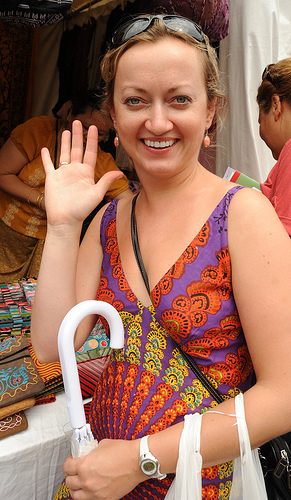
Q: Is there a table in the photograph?
A: Yes, there is a table.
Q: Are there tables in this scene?
A: Yes, there is a table.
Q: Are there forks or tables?
A: Yes, there is a table.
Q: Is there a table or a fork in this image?
A: Yes, there is a table.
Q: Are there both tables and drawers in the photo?
A: No, there is a table but no drawers.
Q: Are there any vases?
A: No, there are no vases.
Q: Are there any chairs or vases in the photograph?
A: No, there are no vases or chairs.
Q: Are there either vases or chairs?
A: No, there are no vases or chairs.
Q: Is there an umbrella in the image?
A: Yes, there is an umbrella.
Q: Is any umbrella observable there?
A: Yes, there is an umbrella.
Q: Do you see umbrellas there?
A: Yes, there is an umbrella.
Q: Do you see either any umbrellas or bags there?
A: Yes, there is an umbrella.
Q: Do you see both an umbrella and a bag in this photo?
A: Yes, there are both an umbrella and a bag.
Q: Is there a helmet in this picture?
A: No, there are no helmets.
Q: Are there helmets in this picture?
A: No, there are no helmets.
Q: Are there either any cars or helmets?
A: No, there are no helmets or cars.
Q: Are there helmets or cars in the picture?
A: No, there are no helmets or cars.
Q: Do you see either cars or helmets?
A: No, there are no helmets or cars.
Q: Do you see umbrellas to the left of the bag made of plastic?
A: Yes, there is an umbrella to the left of the bag.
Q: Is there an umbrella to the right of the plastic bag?
A: No, the umbrella is to the left of the bag.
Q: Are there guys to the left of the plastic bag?
A: No, there is an umbrella to the left of the bag.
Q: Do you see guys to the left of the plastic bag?
A: No, there is an umbrella to the left of the bag.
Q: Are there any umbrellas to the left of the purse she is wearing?
A: Yes, there is an umbrella to the left of the purse.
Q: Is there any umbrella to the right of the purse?
A: No, the umbrella is to the left of the purse.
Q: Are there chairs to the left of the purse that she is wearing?
A: No, there is an umbrella to the left of the purse.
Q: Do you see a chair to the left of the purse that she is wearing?
A: No, there is an umbrella to the left of the purse.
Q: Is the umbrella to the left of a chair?
A: No, the umbrella is to the left of a purse.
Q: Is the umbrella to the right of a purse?
A: No, the umbrella is to the left of a purse.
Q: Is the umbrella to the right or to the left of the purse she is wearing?
A: The umbrella is to the left of the purse.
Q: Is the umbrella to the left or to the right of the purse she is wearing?
A: The umbrella is to the left of the purse.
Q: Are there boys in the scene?
A: No, there are no boys.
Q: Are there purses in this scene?
A: Yes, there is a purse.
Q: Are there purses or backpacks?
A: Yes, there is a purse.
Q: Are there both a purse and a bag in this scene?
A: Yes, there are both a purse and a bag.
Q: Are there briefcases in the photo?
A: No, there are no briefcases.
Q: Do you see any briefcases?
A: No, there are no briefcases.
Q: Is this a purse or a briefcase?
A: This is a purse.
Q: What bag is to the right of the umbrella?
A: The bag is a purse.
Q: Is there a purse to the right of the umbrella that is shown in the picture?
A: Yes, there is a purse to the right of the umbrella.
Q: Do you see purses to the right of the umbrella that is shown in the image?
A: Yes, there is a purse to the right of the umbrella.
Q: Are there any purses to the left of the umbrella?
A: No, the purse is to the right of the umbrella.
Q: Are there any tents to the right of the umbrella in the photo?
A: No, there is a purse to the right of the umbrella.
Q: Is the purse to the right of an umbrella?
A: Yes, the purse is to the right of an umbrella.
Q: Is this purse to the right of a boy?
A: No, the purse is to the right of an umbrella.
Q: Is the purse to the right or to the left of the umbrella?
A: The purse is to the right of the umbrella.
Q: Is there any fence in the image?
A: No, there are no fences.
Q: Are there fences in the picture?
A: No, there are no fences.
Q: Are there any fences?
A: No, there are no fences.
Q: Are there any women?
A: Yes, there is a woman.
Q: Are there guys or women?
A: Yes, there is a woman.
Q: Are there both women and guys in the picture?
A: No, there is a woman but no guys.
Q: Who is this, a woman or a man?
A: This is a woman.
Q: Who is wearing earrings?
A: The woman is wearing earrings.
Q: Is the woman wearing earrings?
A: Yes, the woman is wearing earrings.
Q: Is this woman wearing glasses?
A: No, the woman is wearing earrings.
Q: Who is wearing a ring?
A: The woman is wearing a ring.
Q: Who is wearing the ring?
A: The woman is wearing a ring.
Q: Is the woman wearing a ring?
A: Yes, the woman is wearing a ring.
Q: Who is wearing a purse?
A: The woman is wearing a purse.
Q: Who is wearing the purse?
A: The woman is wearing a purse.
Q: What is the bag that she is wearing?
A: The bag is a purse.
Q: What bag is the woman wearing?
A: The woman is wearing a purse.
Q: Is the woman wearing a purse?
A: Yes, the woman is wearing a purse.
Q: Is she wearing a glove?
A: No, the woman is wearing a purse.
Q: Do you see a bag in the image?
A: Yes, there is a bag.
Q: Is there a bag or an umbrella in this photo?
A: Yes, there is a bag.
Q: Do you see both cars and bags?
A: No, there is a bag but no cars.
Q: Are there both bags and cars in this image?
A: No, there is a bag but no cars.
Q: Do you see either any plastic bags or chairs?
A: Yes, there is a plastic bag.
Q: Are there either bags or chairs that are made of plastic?
A: Yes, the bag is made of plastic.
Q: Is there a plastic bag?
A: Yes, there is a bag that is made of plastic.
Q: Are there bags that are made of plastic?
A: Yes, there is a bag that is made of plastic.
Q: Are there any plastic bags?
A: Yes, there is a bag that is made of plastic.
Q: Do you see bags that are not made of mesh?
A: Yes, there is a bag that is made of plastic.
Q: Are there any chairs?
A: No, there are no chairs.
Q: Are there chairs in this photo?
A: No, there are no chairs.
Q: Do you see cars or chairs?
A: No, there are no chairs or cars.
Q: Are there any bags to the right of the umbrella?
A: Yes, there is a bag to the right of the umbrella.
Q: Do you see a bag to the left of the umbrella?
A: No, the bag is to the right of the umbrella.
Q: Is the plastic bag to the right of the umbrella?
A: Yes, the bag is to the right of the umbrella.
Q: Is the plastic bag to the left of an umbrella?
A: No, the bag is to the right of an umbrella.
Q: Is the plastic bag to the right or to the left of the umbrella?
A: The bag is to the right of the umbrella.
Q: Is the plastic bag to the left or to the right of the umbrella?
A: The bag is to the right of the umbrella.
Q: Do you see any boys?
A: No, there are no boys.